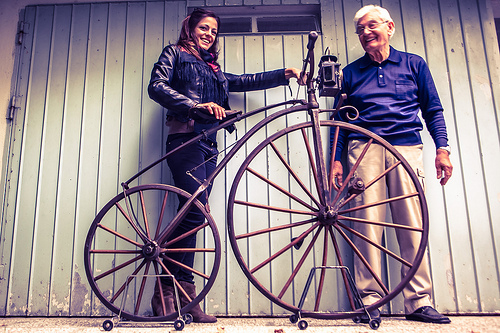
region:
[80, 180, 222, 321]
metal wheel on a bicycle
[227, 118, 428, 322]
large metal wheel on a bicycle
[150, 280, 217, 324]
a woman's brown boots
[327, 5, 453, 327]
an elderly man is standing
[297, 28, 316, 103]
handlebars on an old bike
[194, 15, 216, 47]
face of a woman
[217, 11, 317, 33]
a small thin window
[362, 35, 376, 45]
a man's smiling face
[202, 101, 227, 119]
hand of a woman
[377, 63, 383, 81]
buttons on a man's shirt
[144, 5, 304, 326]
an attractive woman holds the old bike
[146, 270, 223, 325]
fashionable boots on the woman's feet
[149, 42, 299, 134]
the woman wears a leather coat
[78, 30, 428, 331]
an old time bicycle on display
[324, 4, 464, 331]
an old man stands by the bike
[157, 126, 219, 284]
the woman wears sweet tight pants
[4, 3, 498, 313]
a large hinged door behind the people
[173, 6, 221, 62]
the pretty woman is smiling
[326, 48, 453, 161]
the man wears a blue shirt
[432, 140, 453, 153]
the man wears a watch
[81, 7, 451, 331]
a man and woman with a bicycle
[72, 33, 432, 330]
an antique bicycle with a big wheel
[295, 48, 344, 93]
a lantern on a bicycle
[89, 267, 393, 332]
a bicycle on little wheels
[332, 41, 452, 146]
a man in a blue shirt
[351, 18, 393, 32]
a man wearing glasses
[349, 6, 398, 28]
a man with gray hair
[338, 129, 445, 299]
a man wearing tan pants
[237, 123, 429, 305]
spokes on a bicycle tire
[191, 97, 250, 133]
a seat on a bicycle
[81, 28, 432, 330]
rusty metal antique bicycle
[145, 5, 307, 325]
lady in a shiny black leather jacket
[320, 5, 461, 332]
older man with white hair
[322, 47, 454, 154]
indigo button up shirt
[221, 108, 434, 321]
large rusty bicycle wheel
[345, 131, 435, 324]
baggy tan pants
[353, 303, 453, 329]
men's black leather loafers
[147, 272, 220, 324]
women's brown suede boots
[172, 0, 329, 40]
small two paned window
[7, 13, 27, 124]
two metal door hinges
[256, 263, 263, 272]
edge of a wheel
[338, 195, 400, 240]
part of a metal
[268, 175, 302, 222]
part of a wheel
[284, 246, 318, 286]
part of a wheel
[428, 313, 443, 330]
edge of a shoe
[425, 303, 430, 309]
par tof a shoe